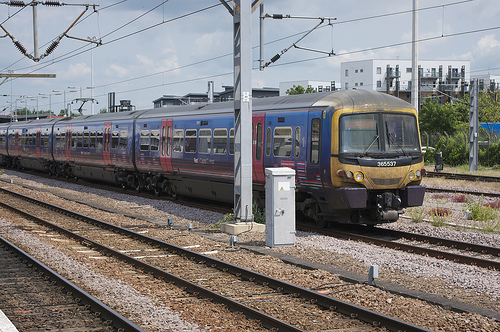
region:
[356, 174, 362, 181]
The left headlight of the train.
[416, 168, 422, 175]
The right headlight of the train.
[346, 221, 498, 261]
The tracks the train is traveling on.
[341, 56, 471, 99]
The white building on the right.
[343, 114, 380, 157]
The left front window of the train.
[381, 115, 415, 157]
The right front window of the train.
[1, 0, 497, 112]
cloud cover in daytime sky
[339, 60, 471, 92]
two floors of flat white building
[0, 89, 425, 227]
commuter train with red double doors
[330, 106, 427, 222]
dirty yellow front of train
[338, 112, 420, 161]
train windshield with two wipers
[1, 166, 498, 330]
multiple sets of train tracks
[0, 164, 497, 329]
gravel in between track rails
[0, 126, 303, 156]
rows of windows on side of train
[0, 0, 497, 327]
cables suspended over train tracks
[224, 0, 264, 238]
a pole color gray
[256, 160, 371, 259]
a gray box of metal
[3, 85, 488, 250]
a train running on the trucks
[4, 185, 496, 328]
rails on the ground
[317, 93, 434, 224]
front parts of the train is yellow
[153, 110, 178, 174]
door of train is red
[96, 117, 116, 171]
door of train is red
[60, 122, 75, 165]
door of train is red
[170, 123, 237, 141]
small windows on side the train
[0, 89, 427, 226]
A multi colored train with yellow front.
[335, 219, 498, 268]
A brown track in front of a train.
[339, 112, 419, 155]
A large windshield on the front of a train.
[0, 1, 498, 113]
A blue sky with white clouds.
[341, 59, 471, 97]
A white building with windows.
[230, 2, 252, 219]
A thick big grey metal support beam.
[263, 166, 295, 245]
A long grey utility box.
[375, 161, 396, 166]
White numbers on a train under the windshield.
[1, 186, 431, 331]
The longest visible brown train track.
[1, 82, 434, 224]
yellow blue and red train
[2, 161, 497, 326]
metal train tracks on railway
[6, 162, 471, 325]
gravel in between train tracks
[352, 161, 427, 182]
two headlights on front of train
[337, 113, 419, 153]
large windshield on train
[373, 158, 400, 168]
white numbers indicating number of train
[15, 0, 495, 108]
blue sky with white clouds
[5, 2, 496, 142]
electrical wires surrounding train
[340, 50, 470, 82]
white building with Evergreen trees in front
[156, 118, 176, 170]
passenger doors are red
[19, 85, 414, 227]
this is a train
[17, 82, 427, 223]
this is a passenger train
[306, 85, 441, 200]
yellow front of train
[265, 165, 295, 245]
the metal box is gray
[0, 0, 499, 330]
the power lines above the tracks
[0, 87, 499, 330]
the train is near the tracks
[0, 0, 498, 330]
the sky above the tracks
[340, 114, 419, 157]
front window of the train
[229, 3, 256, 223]
gray pole on the pavement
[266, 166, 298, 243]
electrical box on the pavement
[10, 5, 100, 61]
power lines on the pavement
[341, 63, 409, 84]
gray building behind the train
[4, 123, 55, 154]
rear wagon of red and blue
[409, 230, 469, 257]
rail train tracks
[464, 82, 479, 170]
gray electric pole on train tracks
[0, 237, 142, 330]
a set of train tracks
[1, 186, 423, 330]
a set of train tracks